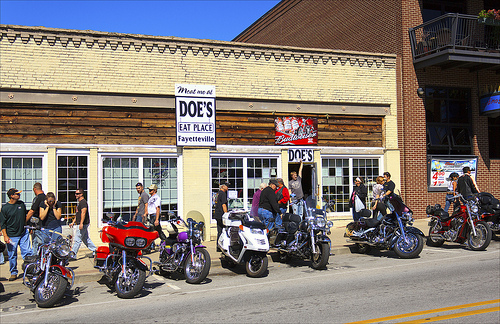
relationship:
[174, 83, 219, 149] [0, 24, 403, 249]
sign on side of building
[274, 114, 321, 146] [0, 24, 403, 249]
sign on side of building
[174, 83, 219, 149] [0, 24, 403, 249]
sign on front of building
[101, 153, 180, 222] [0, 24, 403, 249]
window on front of building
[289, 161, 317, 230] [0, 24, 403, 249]
doorway on side of building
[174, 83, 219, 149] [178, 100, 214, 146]
sign has black lettering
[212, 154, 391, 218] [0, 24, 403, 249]
windows on building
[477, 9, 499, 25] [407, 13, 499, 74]
flower pot on patio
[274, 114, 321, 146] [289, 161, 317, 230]
sign above entrance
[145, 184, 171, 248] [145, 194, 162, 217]
man wearing shirt